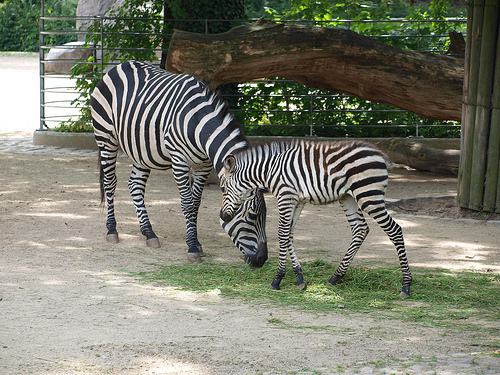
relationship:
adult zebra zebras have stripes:
[89, 60, 269, 270] [236, 164, 415, 250]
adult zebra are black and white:
[89, 60, 269, 270] [225, 162, 407, 280]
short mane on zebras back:
[253, 135, 376, 147] [222, 143, 412, 171]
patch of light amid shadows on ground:
[116, 265, 225, 308] [19, 309, 499, 375]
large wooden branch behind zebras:
[163, 15, 470, 133] [75, 88, 434, 297]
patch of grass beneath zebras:
[108, 255, 421, 335] [54, 142, 421, 301]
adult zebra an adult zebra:
[89, 60, 269, 270] [82, 117, 222, 199]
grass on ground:
[130, 248, 500, 374] [144, 242, 493, 333]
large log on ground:
[204, 105, 499, 194] [356, 102, 486, 154]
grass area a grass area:
[86, 247, 499, 374] [125, 246, 495, 355]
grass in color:
[130, 248, 500, 374] [141, 253, 488, 303]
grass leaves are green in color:
[130, 248, 500, 374] [303, 210, 471, 340]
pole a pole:
[39, 0, 44, 131] [23, 100, 58, 160]